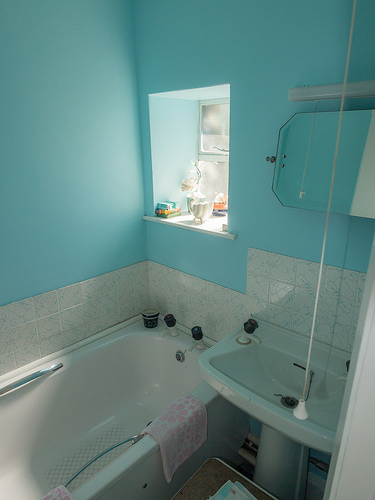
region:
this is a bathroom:
[51, 144, 300, 495]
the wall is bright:
[12, 118, 109, 233]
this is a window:
[136, 85, 234, 227]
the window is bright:
[150, 135, 230, 234]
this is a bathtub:
[56, 358, 150, 466]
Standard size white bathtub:
[1, 308, 251, 498]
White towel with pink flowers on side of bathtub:
[143, 392, 208, 481]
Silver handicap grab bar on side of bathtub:
[0, 362, 65, 400]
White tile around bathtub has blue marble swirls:
[0, 257, 245, 378]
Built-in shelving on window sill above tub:
[142, 82, 244, 241]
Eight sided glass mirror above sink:
[266, 109, 374, 220]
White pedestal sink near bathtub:
[196, 313, 355, 497]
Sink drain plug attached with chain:
[273, 368, 315, 409]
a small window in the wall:
[143, 74, 243, 256]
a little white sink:
[197, 320, 348, 489]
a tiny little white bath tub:
[0, 305, 246, 496]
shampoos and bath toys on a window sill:
[154, 154, 233, 232]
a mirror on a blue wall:
[267, 105, 372, 222]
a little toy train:
[153, 191, 185, 223]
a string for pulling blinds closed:
[291, 0, 359, 433]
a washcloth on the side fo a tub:
[135, 394, 213, 484]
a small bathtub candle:
[135, 301, 165, 332]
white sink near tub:
[221, 313, 312, 418]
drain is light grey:
[273, 379, 305, 404]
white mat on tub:
[24, 410, 134, 497]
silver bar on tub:
[7, 352, 76, 406]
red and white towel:
[132, 393, 230, 481]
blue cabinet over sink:
[263, 92, 331, 213]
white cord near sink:
[288, 208, 333, 427]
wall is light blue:
[157, 41, 230, 62]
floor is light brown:
[182, 468, 222, 493]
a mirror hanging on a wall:
[261, 105, 374, 220]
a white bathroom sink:
[197, 312, 340, 456]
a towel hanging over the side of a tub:
[149, 387, 207, 485]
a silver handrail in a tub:
[60, 432, 146, 497]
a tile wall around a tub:
[0, 259, 204, 383]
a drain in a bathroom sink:
[277, 394, 300, 408]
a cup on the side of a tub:
[140, 302, 160, 329]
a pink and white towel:
[149, 393, 205, 461]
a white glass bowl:
[183, 197, 213, 224]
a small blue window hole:
[143, 79, 241, 249]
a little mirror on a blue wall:
[266, 104, 371, 225]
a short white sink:
[207, 320, 346, 492]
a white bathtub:
[36, 348, 218, 480]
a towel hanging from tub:
[134, 400, 210, 488]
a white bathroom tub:
[56, 324, 177, 433]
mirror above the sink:
[272, 115, 374, 211]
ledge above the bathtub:
[150, 202, 229, 238]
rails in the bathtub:
[0, 365, 144, 485]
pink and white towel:
[135, 393, 208, 473]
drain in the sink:
[280, 391, 298, 408]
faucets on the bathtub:
[155, 311, 209, 359]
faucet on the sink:
[232, 312, 264, 347]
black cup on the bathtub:
[141, 307, 163, 328]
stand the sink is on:
[253, 427, 300, 485]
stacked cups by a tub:
[142, 306, 159, 325]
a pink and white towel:
[138, 400, 208, 477]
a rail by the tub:
[48, 437, 140, 488]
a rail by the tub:
[0, 361, 60, 415]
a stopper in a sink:
[285, 387, 298, 409]